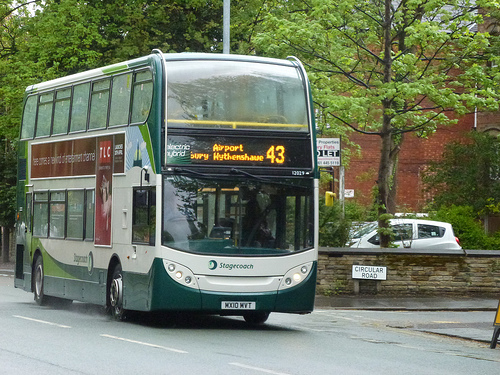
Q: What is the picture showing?
A: It is showing a road.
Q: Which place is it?
A: It is a road.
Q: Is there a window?
A: Yes, there is a window.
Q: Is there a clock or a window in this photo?
A: Yes, there is a window.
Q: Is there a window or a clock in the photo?
A: Yes, there is a window.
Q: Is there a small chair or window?
A: Yes, there is a small window.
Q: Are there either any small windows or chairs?
A: Yes, there is a small window.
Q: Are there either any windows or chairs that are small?
A: Yes, the window is small.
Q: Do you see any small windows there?
A: Yes, there is a small window.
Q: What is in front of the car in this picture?
A: The wall is in front of the car.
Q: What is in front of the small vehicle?
A: The wall is in front of the car.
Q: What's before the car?
A: The wall is in front of the car.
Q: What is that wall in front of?
A: The wall is in front of the car.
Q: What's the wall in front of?
A: The wall is in front of the car.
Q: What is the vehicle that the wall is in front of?
A: The vehicle is a car.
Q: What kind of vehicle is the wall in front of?
A: The wall is in front of the car.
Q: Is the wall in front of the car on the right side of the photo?
A: Yes, the wall is in front of the car.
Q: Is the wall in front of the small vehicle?
A: Yes, the wall is in front of the car.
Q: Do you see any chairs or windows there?
A: Yes, there is a window.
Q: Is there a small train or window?
A: Yes, there is a small window.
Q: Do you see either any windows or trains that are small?
A: Yes, the window is small.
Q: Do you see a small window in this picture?
A: Yes, there is a small window.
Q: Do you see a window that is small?
A: Yes, there is a window that is small.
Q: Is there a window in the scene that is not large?
A: Yes, there is a small window.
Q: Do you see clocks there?
A: No, there are no clocks.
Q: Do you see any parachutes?
A: No, there are no parachutes.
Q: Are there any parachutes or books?
A: No, there are no parachutes or books.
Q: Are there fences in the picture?
A: No, there are no fences.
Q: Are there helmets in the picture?
A: No, there are no helmets.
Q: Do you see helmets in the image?
A: No, there are no helmets.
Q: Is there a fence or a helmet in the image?
A: No, there are no helmets or fences.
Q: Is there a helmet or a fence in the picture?
A: No, there are no helmets or fences.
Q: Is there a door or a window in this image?
A: Yes, there is a window.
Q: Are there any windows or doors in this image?
A: Yes, there is a window.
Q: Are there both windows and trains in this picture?
A: No, there is a window but no trains.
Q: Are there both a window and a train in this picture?
A: No, there is a window but no trains.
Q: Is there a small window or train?
A: Yes, there is a small window.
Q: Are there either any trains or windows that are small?
A: Yes, the window is small.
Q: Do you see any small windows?
A: Yes, there is a small window.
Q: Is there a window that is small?
A: Yes, there is a window that is small.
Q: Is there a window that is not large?
A: Yes, there is a small window.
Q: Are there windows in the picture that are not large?
A: Yes, there is a small window.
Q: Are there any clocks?
A: No, there are no clocks.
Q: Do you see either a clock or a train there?
A: No, there are no clocks or trains.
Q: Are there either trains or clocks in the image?
A: No, there are no clocks or trains.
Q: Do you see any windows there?
A: Yes, there is a window.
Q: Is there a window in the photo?
A: Yes, there is a window.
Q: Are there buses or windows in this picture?
A: Yes, there is a window.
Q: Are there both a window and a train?
A: No, there is a window but no trains.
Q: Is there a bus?
A: Yes, there is a bus.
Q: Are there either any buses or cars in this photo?
A: Yes, there is a bus.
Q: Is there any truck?
A: No, there are no trucks.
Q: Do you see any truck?
A: No, there are no trucks.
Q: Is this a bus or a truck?
A: This is a bus.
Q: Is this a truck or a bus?
A: This is a bus.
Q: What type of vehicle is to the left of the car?
A: The vehicle is a bus.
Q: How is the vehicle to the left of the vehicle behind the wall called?
A: The vehicle is a bus.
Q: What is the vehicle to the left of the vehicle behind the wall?
A: The vehicle is a bus.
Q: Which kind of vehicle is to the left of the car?
A: The vehicle is a bus.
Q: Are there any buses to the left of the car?
A: Yes, there is a bus to the left of the car.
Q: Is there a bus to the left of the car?
A: Yes, there is a bus to the left of the car.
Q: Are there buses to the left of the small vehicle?
A: Yes, there is a bus to the left of the car.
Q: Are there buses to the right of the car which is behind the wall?
A: No, the bus is to the left of the car.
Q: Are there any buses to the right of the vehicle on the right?
A: No, the bus is to the left of the car.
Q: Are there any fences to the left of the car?
A: No, there is a bus to the left of the car.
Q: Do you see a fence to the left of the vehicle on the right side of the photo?
A: No, there is a bus to the left of the car.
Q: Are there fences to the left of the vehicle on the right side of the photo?
A: No, there is a bus to the left of the car.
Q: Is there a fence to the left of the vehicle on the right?
A: No, there is a bus to the left of the car.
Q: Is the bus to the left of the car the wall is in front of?
A: Yes, the bus is to the left of the car.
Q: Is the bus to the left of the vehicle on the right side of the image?
A: Yes, the bus is to the left of the car.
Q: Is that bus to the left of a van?
A: No, the bus is to the left of the car.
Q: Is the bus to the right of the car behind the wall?
A: No, the bus is to the left of the car.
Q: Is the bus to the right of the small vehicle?
A: No, the bus is to the left of the car.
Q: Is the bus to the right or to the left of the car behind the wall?
A: The bus is to the left of the car.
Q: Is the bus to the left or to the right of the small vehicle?
A: The bus is to the left of the car.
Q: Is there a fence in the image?
A: No, there are no fences.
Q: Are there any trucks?
A: No, there are no trucks.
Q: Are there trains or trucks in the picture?
A: No, there are no trucks or trains.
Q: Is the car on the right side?
A: Yes, the car is on the right of the image.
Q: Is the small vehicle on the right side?
A: Yes, the car is on the right of the image.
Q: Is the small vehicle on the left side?
A: No, the car is on the right of the image.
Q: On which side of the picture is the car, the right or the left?
A: The car is on the right of the image.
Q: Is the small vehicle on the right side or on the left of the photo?
A: The car is on the right of the image.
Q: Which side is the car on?
A: The car is on the right of the image.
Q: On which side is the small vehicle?
A: The car is on the right of the image.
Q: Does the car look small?
A: Yes, the car is small.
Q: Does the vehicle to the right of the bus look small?
A: Yes, the car is small.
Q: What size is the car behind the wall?
A: The car is small.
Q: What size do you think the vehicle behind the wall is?
A: The car is small.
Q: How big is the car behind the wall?
A: The car is small.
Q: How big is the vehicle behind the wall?
A: The car is small.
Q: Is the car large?
A: No, the car is small.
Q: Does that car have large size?
A: No, the car is small.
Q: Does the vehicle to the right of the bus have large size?
A: No, the car is small.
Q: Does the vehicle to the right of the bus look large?
A: No, the car is small.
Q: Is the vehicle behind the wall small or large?
A: The car is small.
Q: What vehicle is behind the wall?
A: The vehicle is a car.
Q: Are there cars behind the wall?
A: Yes, there is a car behind the wall.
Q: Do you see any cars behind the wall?
A: Yes, there is a car behind the wall.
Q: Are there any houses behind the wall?
A: No, there is a car behind the wall.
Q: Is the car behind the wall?
A: Yes, the car is behind the wall.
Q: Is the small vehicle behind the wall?
A: Yes, the car is behind the wall.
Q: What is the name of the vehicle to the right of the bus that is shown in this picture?
A: The vehicle is a car.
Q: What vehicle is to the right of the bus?
A: The vehicle is a car.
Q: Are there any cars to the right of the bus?
A: Yes, there is a car to the right of the bus.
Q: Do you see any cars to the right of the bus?
A: Yes, there is a car to the right of the bus.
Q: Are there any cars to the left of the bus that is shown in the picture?
A: No, the car is to the right of the bus.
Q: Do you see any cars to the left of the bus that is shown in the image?
A: No, the car is to the right of the bus.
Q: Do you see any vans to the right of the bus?
A: No, there is a car to the right of the bus.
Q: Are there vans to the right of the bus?
A: No, there is a car to the right of the bus.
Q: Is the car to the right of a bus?
A: Yes, the car is to the right of a bus.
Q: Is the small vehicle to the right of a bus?
A: Yes, the car is to the right of a bus.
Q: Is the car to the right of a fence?
A: No, the car is to the right of a bus.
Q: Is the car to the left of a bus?
A: No, the car is to the right of a bus.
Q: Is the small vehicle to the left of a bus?
A: No, the car is to the right of a bus.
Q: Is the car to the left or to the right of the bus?
A: The car is to the right of the bus.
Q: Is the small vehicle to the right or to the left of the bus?
A: The car is to the right of the bus.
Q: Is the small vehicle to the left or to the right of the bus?
A: The car is to the right of the bus.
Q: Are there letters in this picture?
A: Yes, there are letters.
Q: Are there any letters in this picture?
A: Yes, there are letters.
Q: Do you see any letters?
A: Yes, there are letters.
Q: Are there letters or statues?
A: Yes, there are letters.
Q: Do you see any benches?
A: No, there are no benches.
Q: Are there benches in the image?
A: No, there are no benches.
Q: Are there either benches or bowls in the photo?
A: No, there are no benches or bowls.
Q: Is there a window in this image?
A: Yes, there is a window.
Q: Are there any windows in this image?
A: Yes, there is a window.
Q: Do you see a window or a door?
A: Yes, there is a window.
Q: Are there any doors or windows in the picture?
A: Yes, there is a window.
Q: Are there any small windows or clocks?
A: Yes, there is a small window.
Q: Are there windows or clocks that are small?
A: Yes, the window is small.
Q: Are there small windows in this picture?
A: Yes, there is a small window.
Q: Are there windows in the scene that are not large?
A: Yes, there is a small window.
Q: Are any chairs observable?
A: No, there are no chairs.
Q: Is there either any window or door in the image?
A: Yes, there is a window.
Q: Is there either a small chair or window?
A: Yes, there is a small window.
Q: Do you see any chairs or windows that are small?
A: Yes, the window is small.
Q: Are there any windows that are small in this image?
A: Yes, there is a small window.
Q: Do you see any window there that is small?
A: Yes, there is a small window.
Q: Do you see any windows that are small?
A: Yes, there is a window that is small.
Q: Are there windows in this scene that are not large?
A: Yes, there is a small window.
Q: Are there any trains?
A: No, there are no trains.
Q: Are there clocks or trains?
A: No, there are no trains or clocks.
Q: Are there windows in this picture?
A: Yes, there is a window.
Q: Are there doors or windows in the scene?
A: Yes, there is a window.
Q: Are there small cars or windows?
A: Yes, there is a small window.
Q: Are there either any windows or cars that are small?
A: Yes, the window is small.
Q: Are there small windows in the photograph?
A: Yes, there is a small window.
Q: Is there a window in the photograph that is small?
A: Yes, there is a window that is small.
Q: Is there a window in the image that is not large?
A: Yes, there is a small window.